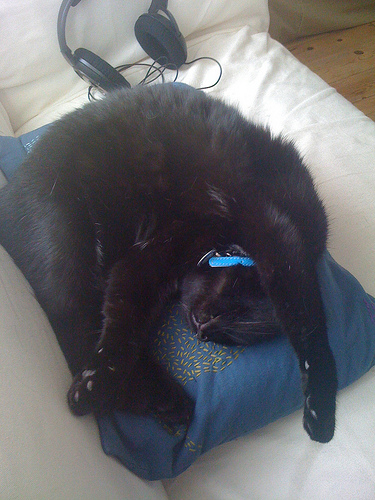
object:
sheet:
[99, 417, 200, 484]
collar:
[193, 244, 261, 268]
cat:
[0, 79, 337, 449]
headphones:
[57, 0, 189, 94]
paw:
[66, 348, 118, 417]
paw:
[298, 370, 339, 444]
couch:
[2, 7, 373, 497]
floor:
[270, 0, 375, 122]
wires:
[89, 55, 222, 102]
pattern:
[146, 297, 246, 455]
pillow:
[0, 84, 375, 484]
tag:
[197, 249, 215, 266]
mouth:
[187, 301, 223, 332]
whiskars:
[232, 330, 278, 336]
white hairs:
[206, 187, 229, 217]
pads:
[81, 367, 97, 380]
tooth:
[211, 315, 214, 318]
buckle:
[215, 251, 232, 258]